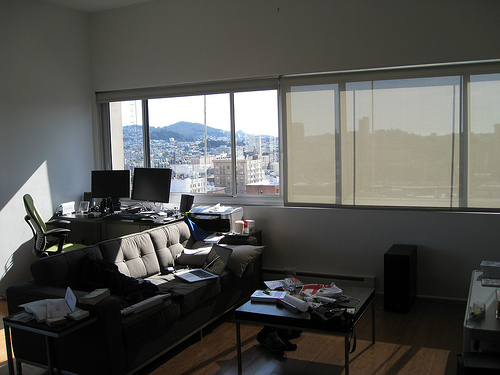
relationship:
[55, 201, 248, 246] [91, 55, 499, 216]
desk by window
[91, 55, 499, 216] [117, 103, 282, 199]
window showing city view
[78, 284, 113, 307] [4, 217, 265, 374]
book on couch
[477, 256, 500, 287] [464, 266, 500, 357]
wii games on table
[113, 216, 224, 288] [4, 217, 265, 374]
sun shining on couch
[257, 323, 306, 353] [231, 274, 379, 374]
tennis shoes under coffee table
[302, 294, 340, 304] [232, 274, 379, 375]
wii controler on table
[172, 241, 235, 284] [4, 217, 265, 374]
laptop on couch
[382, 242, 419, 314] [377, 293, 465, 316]
speaker on foor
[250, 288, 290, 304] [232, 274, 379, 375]
book on table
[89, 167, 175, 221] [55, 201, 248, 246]
computers on desk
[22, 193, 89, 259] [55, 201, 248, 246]
chair facing desk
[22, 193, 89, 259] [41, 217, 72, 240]
chair with armrest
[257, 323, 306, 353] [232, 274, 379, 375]
shoes under table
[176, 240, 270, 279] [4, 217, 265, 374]
pillow on couch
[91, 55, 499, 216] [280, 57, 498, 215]
window with curtains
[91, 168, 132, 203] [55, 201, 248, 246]
computer monitor on desk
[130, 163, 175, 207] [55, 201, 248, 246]
computer monitor on desk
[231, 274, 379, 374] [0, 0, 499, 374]
coffee table in room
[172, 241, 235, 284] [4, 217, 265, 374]
laptop computer on couch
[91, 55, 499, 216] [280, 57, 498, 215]
window with blinds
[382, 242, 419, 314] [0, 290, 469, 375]
speaker on floor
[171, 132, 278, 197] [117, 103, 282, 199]
building in background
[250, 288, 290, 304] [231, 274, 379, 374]
book on talbe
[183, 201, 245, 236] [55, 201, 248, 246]
printer on desk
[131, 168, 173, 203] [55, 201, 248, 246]
computer monitor on desk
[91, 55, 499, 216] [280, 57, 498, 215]
window with shades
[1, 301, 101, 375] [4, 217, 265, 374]
end table by sofa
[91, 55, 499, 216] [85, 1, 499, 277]
window along wall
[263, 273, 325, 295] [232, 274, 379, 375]
trash on table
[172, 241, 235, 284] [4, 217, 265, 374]
aptop on couch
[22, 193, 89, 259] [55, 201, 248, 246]
chair at desk